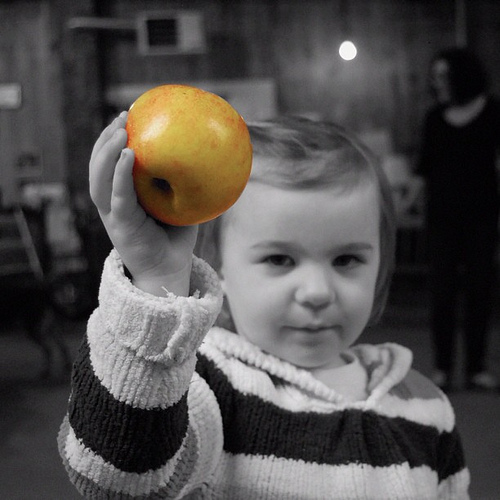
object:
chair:
[0, 189, 87, 384]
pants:
[429, 267, 488, 377]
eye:
[332, 253, 361, 267]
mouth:
[282, 323, 342, 338]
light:
[338, 40, 357, 61]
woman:
[401, 46, 500, 395]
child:
[56, 109, 471, 499]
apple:
[124, 83, 253, 226]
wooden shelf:
[67, 16, 137, 29]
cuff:
[98, 247, 224, 368]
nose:
[293, 262, 335, 306]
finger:
[110, 147, 137, 215]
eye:
[261, 254, 294, 267]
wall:
[1, 0, 500, 202]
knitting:
[260, 400, 275, 417]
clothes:
[412, 95, 499, 374]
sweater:
[57, 251, 472, 499]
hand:
[89, 110, 199, 279]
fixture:
[337, 39, 359, 62]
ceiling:
[0, 0, 499, 15]